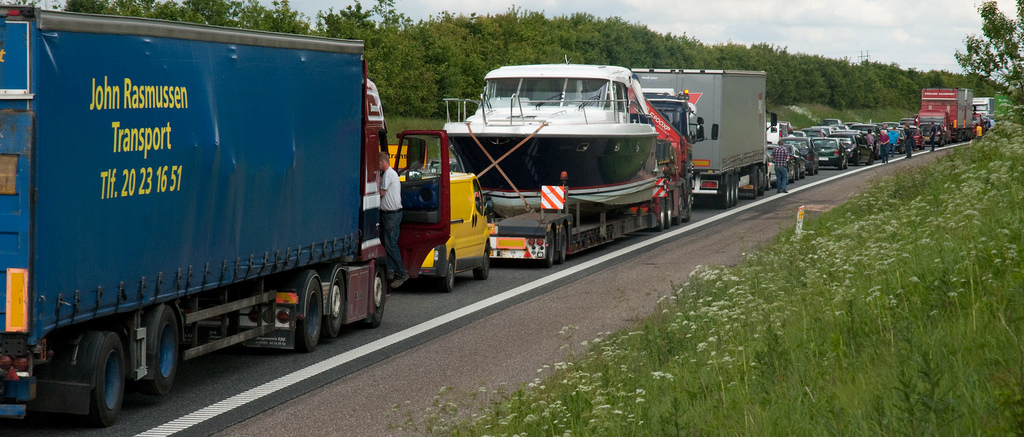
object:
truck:
[622, 68, 765, 209]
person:
[380, 152, 408, 288]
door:
[380, 130, 456, 276]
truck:
[0, 6, 451, 429]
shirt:
[377, 167, 402, 211]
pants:
[381, 212, 408, 278]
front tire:
[370, 265, 387, 328]